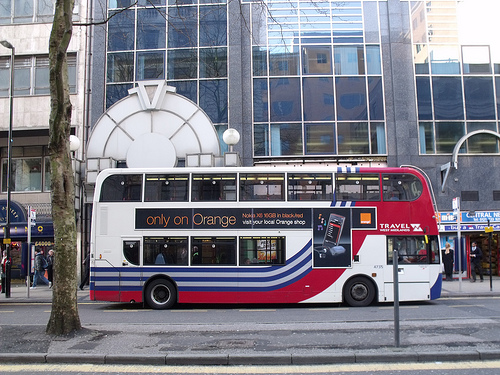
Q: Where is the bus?
A: Parked by the sidewalk.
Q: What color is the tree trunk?
A: Brown.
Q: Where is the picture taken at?
A: On a city street.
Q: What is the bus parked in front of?
A: A building.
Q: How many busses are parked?
A: One.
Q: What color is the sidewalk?
A: Grey.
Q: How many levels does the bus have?
A: Two.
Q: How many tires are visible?
A: Two.